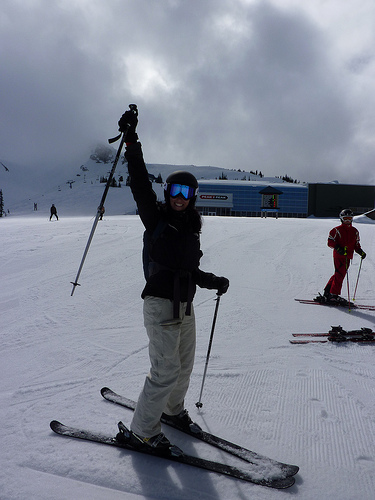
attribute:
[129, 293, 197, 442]
pants — white, gray, light colored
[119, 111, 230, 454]
woman — skiing, smiling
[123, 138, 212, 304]
jacket — black, blue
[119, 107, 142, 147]
glove — black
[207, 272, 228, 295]
glove — black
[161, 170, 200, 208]
helmet — black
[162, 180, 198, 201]
goggles — blue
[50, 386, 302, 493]
skis — black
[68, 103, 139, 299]
ski pole — silver, black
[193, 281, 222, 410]
ski pole — silver, black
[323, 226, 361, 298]
outfit — red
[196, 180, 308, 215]
building — blue, white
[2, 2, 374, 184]
clouds — dark